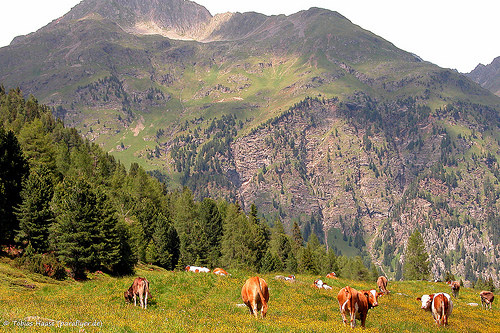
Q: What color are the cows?
A: Brown.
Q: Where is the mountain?
A: In the back behind the cows.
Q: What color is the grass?
A: Green.